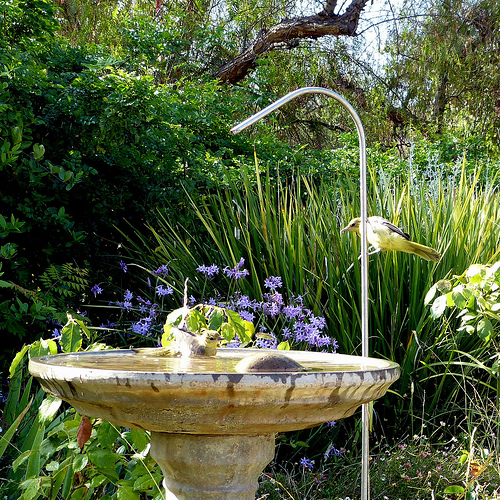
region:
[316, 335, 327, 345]
light purple colored flower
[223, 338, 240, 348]
light purple colored flower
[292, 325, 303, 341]
light purple colored flower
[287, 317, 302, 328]
light purple colored flower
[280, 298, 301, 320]
light purple colored flower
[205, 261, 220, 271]
light purple colored flower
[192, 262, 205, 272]
light purple colored flower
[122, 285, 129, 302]
light purple colored flower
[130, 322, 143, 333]
light purple colored flower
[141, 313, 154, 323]
light purple colored flower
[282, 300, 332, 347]
blue flowers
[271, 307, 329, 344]
the flowers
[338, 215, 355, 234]
a bird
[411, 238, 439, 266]
the tail of the bird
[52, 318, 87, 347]
a green leaf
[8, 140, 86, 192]
a green bush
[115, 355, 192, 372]
water in the fountain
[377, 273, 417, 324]
the green tall plant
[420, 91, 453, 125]
a tall tree branch on the tree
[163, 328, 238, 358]
Small bird sitting in water.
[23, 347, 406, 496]
Cement water fountain.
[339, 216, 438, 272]
A bird standing on side of pole.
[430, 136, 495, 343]
Sun shining on green plants.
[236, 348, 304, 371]
A stone in the water.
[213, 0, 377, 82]
Dark brown tree bark.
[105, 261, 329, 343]
Beautiful lavender colored flowers.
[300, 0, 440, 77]
The blue sky behind tree branches.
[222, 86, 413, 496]
A curved slender pole.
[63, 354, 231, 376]
Sun light reflecting on the water.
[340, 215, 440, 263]
Wild bird hanging onto pole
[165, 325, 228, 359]
Bird sitting in a birdbath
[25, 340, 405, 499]
Cement birdbath filled with water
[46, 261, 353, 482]
Small purple flowers behind birdbath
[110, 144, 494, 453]
Tall grass in the background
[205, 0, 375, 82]
Large bare tree limb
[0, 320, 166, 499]
Leaves beside birdbath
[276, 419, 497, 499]
Small pink flowers behind pole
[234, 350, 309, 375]
Round curve in birdbath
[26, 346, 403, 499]
a stone bird bath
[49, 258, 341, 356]
a bunch of purple flowers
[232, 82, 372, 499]
a silver crook type of thing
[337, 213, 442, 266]
a yellow bird with a black wing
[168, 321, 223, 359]
a bird sitting in the water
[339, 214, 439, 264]
a bird on a silver pole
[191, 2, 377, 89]
a crooked tree branch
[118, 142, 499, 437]
a bush with long pointy leaves